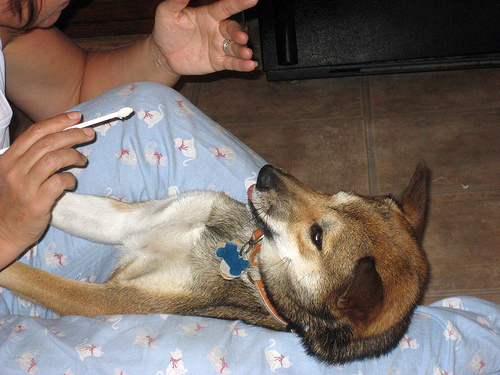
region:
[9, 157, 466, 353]
a dog in middle of the legs of a person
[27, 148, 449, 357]
dog is brown and white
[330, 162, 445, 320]
ears of dog are brown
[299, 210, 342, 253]
eye of dog is black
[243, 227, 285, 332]
collar of dog is orange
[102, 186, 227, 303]
chest of dog is white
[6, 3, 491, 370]
person wears long pants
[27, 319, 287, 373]
pants has white cat designs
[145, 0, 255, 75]
a silver ring in left hand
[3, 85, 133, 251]
a swab on right hand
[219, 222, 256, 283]
dog has dog tags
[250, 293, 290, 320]
dog is wearing a collar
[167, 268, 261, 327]
dog is white, brown and black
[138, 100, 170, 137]
white cat on her pajama pants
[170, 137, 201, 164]
cat has a red bow on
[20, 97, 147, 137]
woman is holding a dog tooth brush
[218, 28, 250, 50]
woman has ring on finger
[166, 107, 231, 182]
pajama pants are light blue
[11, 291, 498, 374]
woman is sitting on the floor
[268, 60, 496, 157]
floor has brown squares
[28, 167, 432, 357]
Dog on woman's lap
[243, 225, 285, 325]
Orange neck tie on dog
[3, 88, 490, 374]
Woman wearing blue pajamas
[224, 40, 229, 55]
Silver ring on woman's finger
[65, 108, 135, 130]
Woman holding ear bud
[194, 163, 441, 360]
Brown and black dog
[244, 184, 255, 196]
Tip of dog's tongue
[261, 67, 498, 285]
Square patterns on floor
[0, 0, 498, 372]
Woman sitting on the floor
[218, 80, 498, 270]
Floor made of wood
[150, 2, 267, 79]
a hand of a woman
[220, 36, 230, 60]
a ring on a finger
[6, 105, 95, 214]
the fingers of a hand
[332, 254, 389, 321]
the ear of a dog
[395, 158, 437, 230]
the ear of a dog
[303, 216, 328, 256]
the eye of a dog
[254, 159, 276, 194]
the nose of a dog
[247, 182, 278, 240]
the mouth of a dog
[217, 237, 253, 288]
the tags for a dog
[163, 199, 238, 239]
the fur of a dog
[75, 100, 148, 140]
White cotton swab in hand.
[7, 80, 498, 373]
Blue pajama bottoms.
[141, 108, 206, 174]
Cats pattern on material.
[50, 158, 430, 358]
Dog laying on lap.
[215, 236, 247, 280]
Blue dog bone tag.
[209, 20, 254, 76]
Silver ring on finger.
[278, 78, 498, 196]
Brown tile design on floor.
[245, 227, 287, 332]
Leather collar on dog.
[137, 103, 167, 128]
Red bow on cat.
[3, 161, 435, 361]
Brown, white, black, and gray colors on dog.